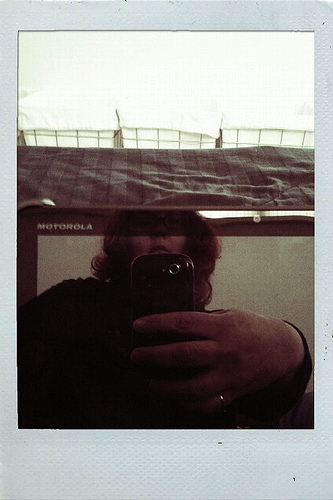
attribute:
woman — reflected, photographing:
[16, 207, 313, 428]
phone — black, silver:
[130, 249, 195, 373]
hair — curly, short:
[89, 203, 221, 313]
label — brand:
[34, 221, 97, 233]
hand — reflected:
[132, 307, 307, 419]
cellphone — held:
[17, 198, 316, 429]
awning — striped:
[16, 143, 316, 208]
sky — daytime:
[17, 30, 312, 150]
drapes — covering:
[17, 144, 313, 207]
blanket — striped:
[16, 141, 315, 208]